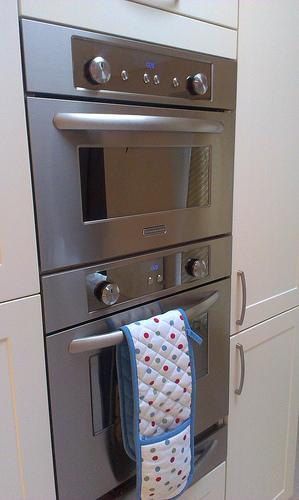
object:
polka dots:
[161, 364, 169, 371]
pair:
[16, 14, 238, 499]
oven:
[17, 17, 238, 274]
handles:
[235, 271, 247, 327]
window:
[77, 136, 211, 226]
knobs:
[88, 52, 112, 86]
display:
[119, 68, 180, 92]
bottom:
[98, 406, 230, 499]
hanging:
[67, 291, 219, 357]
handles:
[52, 108, 224, 136]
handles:
[234, 343, 246, 396]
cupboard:
[228, 0, 298, 337]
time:
[144, 61, 156, 72]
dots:
[169, 330, 175, 341]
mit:
[116, 304, 204, 499]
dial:
[187, 72, 209, 98]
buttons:
[171, 75, 181, 90]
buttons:
[154, 271, 165, 287]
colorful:
[133, 312, 195, 445]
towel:
[116, 307, 204, 497]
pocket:
[135, 414, 194, 498]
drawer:
[175, 460, 226, 499]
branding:
[140, 222, 166, 238]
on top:
[19, 17, 238, 111]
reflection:
[187, 144, 212, 206]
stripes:
[186, 190, 210, 209]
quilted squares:
[167, 346, 182, 366]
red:
[143, 329, 149, 342]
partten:
[158, 359, 175, 382]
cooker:
[26, 94, 234, 276]